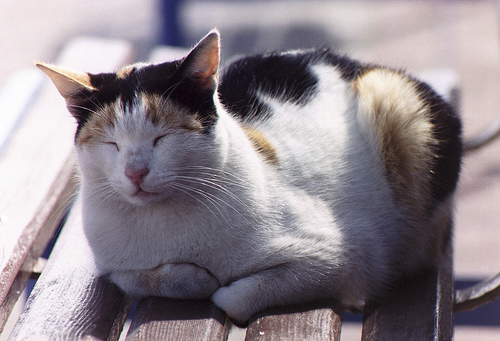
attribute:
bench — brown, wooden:
[8, 35, 466, 337]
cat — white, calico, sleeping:
[31, 35, 471, 320]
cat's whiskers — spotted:
[28, 42, 448, 292]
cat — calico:
[52, 41, 493, 263]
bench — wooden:
[42, 288, 463, 338]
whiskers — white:
[31, 170, 275, 238]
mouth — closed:
[121, 176, 152, 201]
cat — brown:
[53, 45, 448, 317]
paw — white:
[201, 259, 271, 340]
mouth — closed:
[128, 188, 160, 200]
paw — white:
[145, 261, 219, 300]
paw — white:
[115, 260, 217, 302]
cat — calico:
[22, 21, 457, 325]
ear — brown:
[30, 58, 97, 111]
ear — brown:
[178, 19, 238, 86]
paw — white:
[212, 280, 259, 327]